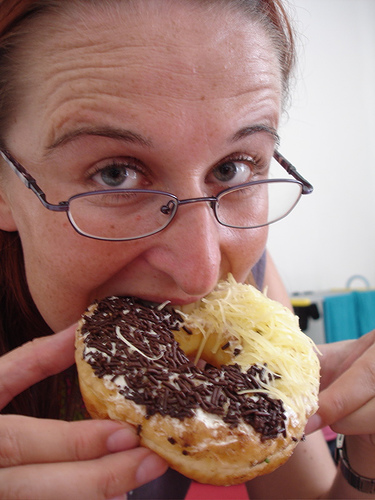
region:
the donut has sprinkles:
[60, 272, 367, 491]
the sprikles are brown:
[117, 327, 196, 400]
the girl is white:
[11, 4, 298, 350]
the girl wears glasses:
[46, 173, 332, 244]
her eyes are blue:
[93, 155, 139, 195]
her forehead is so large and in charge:
[41, 19, 290, 132]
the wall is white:
[322, 69, 373, 160]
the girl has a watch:
[324, 416, 373, 499]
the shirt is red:
[5, 276, 38, 337]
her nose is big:
[147, 196, 235, 302]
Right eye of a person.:
[81, 156, 146, 191]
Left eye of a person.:
[201, 155, 259, 187]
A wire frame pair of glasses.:
[51, 178, 323, 234]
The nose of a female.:
[150, 201, 219, 294]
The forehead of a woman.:
[18, 5, 283, 158]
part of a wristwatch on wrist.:
[328, 427, 373, 494]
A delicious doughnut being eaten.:
[68, 267, 312, 472]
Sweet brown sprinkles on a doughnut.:
[73, 318, 224, 420]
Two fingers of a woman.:
[45, 420, 161, 487]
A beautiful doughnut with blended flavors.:
[88, 297, 316, 464]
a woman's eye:
[85, 155, 155, 194]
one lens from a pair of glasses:
[66, 186, 179, 243]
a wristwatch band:
[334, 429, 374, 495]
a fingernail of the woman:
[104, 424, 140, 452]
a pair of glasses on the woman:
[0, 142, 313, 242]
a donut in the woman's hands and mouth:
[70, 271, 324, 487]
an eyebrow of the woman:
[38, 123, 153, 157]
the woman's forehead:
[19, 6, 282, 126]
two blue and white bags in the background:
[286, 271, 372, 344]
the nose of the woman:
[140, 175, 222, 298]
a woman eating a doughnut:
[29, 8, 364, 482]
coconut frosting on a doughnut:
[255, 314, 286, 364]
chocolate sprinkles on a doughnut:
[178, 378, 224, 409]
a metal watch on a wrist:
[332, 437, 372, 491]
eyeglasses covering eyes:
[13, 137, 314, 239]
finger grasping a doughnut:
[3, 328, 149, 492]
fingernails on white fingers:
[110, 428, 168, 479]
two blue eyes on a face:
[98, 147, 266, 192]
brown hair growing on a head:
[262, 6, 297, 43]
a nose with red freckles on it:
[152, 224, 233, 297]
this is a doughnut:
[95, 296, 314, 464]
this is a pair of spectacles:
[64, 185, 306, 223]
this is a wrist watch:
[333, 435, 369, 492]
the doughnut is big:
[102, 310, 306, 417]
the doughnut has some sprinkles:
[119, 317, 306, 398]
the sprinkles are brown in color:
[113, 324, 148, 368]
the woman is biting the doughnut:
[107, 293, 257, 320]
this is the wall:
[323, 165, 359, 246]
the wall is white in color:
[316, 225, 366, 256]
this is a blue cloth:
[331, 297, 370, 328]